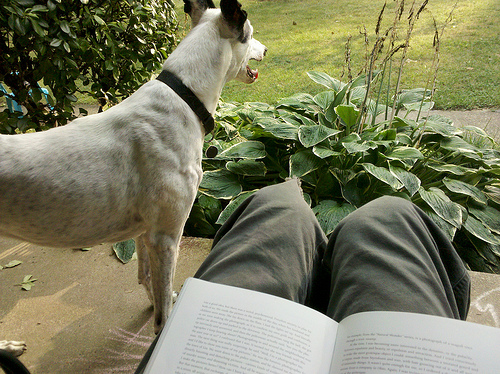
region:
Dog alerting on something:
[157, 0, 284, 87]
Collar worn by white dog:
[147, 56, 227, 146]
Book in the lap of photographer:
[130, 275, 497, 372]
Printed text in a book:
[185, 305, 315, 361]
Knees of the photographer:
[192, 161, 474, 319]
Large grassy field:
[271, 5, 469, 95]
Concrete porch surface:
[15, 242, 125, 355]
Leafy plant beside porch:
[221, 91, 496, 252]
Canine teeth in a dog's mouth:
[250, 61, 261, 77]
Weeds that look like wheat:
[325, 0, 460, 78]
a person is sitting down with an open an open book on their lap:
[134, 182, 499, 372]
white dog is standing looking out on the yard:
[1, 0, 266, 339]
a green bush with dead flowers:
[216, 70, 498, 260]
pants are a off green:
[201, 181, 474, 326]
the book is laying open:
[138, 275, 498, 372]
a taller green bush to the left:
[1, 0, 182, 130]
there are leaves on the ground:
[2, 251, 40, 298]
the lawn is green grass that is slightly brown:
[172, 1, 497, 109]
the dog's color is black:
[151, 61, 211, 131]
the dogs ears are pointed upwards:
[160, 0, 268, 102]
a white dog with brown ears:
[83, 0, 273, 180]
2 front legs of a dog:
[130, 195, 187, 328]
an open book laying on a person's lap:
[177, 244, 477, 369]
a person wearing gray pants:
[230, 190, 450, 301]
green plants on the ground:
[278, 93, 496, 201]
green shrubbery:
[12, 10, 141, 87]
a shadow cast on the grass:
[285, 18, 342, 69]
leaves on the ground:
[6, 236, 137, 297]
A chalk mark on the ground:
[467, 279, 497, 329]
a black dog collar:
[152, 62, 224, 139]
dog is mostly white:
[38, 46, 205, 263]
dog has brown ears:
[168, 9, 260, 43]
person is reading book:
[184, 260, 429, 372]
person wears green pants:
[217, 176, 469, 353]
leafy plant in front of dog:
[170, 70, 437, 200]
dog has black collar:
[143, 61, 245, 161]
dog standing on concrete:
[6, 233, 178, 370]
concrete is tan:
[2, 253, 185, 366]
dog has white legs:
[138, 229, 183, 329]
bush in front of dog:
[0, 2, 133, 95]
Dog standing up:
[0, 3, 275, 354]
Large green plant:
[200, 73, 495, 218]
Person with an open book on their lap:
[127, 177, 491, 372]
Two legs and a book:
[162, 170, 480, 370]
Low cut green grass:
[266, 3, 493, 112]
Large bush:
[2, 0, 178, 127]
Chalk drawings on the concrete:
[47, 305, 162, 368]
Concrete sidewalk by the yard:
[389, 65, 498, 184]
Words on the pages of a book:
[150, 288, 487, 365]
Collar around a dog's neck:
[134, 0, 270, 179]